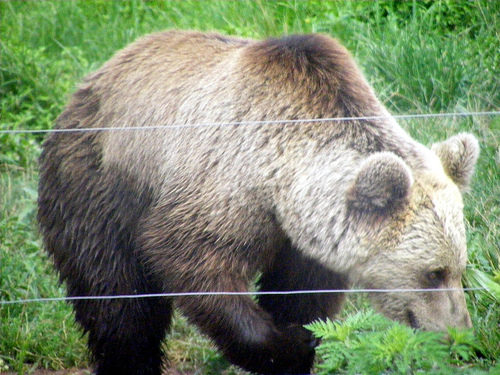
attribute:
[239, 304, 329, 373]
paws — dark brown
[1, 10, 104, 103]
grass — green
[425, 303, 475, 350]
nose — brown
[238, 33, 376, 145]
streak — brown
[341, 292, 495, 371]
grass — leafy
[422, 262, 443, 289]
eye — dark